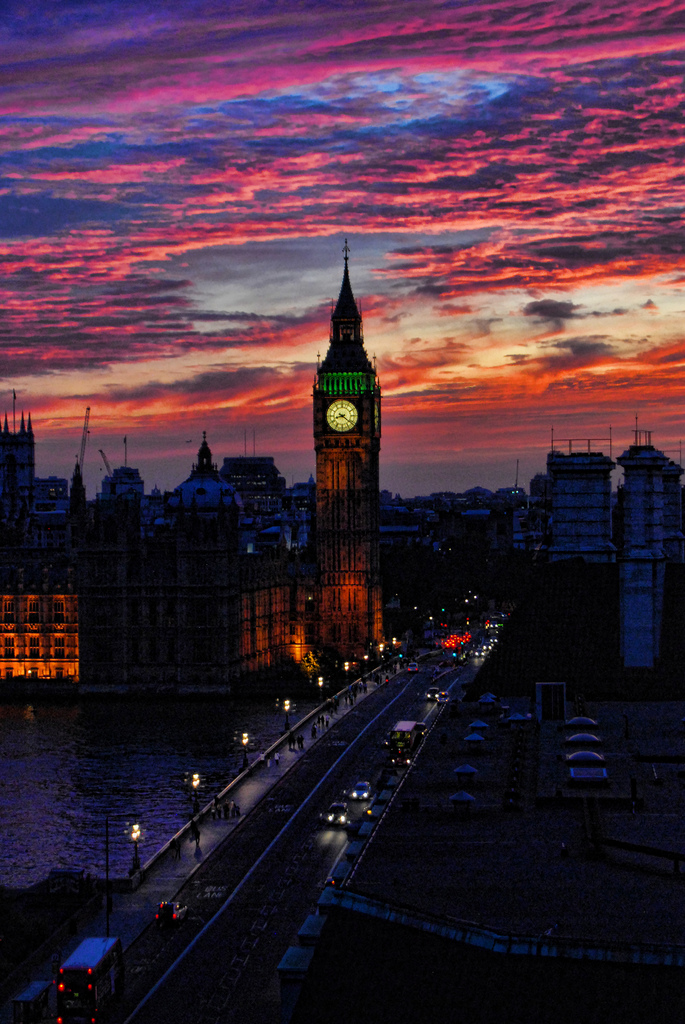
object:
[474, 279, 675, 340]
cloud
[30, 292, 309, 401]
cloud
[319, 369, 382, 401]
lights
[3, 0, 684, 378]
sky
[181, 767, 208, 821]
street light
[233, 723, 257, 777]
street light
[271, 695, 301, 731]
street light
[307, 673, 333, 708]
street light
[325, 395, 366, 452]
clock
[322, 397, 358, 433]
clock face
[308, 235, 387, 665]
tower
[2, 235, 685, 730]
city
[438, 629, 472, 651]
car group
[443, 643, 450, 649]
tail light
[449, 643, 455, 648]
tail light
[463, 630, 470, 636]
tail light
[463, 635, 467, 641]
tail light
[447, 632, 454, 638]
tail light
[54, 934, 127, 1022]
bus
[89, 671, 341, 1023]
road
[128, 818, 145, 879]
street light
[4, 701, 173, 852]
water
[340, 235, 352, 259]
pinnacle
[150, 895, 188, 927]
car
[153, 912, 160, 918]
light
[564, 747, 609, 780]
car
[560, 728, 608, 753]
car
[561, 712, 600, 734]
car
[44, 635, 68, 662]
window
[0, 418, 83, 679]
building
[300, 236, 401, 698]
building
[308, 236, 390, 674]
clock tower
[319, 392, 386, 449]
clocks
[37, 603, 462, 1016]
street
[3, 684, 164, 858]
river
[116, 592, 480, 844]
lights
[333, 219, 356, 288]
spire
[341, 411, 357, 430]
hands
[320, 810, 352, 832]
headlights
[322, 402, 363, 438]
numerals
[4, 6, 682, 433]
clouds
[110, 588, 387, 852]
lamps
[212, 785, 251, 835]
people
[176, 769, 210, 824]
street lamp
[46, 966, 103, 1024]
lights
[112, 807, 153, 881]
street lamps